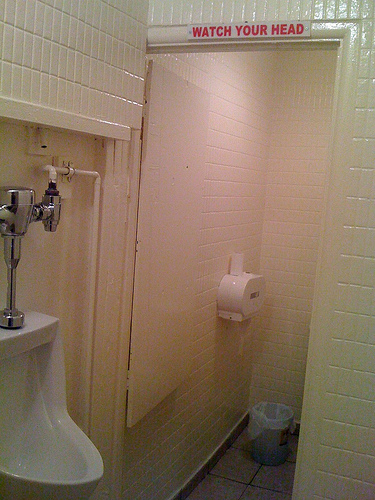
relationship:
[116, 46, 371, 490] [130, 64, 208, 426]
stall has door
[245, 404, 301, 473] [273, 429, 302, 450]
waste can has label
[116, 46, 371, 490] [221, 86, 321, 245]
latrine has a part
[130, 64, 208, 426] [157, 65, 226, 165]
door has a section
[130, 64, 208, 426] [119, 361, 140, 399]
door has hinge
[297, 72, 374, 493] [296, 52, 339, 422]
wall has edge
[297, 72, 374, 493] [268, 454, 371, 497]
wall has bottom part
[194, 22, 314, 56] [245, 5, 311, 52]
notice has a part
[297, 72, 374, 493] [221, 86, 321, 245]
wall has a part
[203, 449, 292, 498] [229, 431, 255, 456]
floor has a part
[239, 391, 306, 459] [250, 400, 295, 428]
bin has edge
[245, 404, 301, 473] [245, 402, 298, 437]
trashcan has a bag liner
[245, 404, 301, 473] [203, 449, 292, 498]
trash can on floor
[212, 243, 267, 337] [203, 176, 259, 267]
toilet paper holder on tile wall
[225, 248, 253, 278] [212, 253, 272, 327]
roll holds toilet paper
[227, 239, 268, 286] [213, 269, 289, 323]
toilet paper atop holder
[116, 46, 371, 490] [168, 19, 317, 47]
door frame has sign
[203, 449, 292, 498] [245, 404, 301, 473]
floor has on it a trash can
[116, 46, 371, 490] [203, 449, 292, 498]
bathroom has floor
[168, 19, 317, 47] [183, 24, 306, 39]
sign has red letters